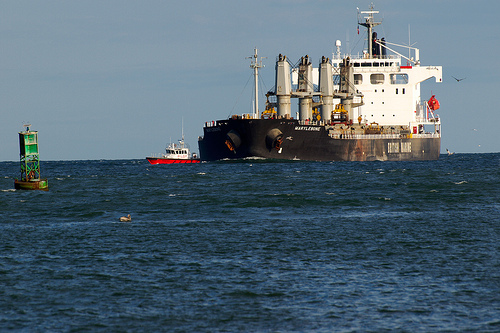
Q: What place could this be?
A: It is an ocean.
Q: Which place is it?
A: It is an ocean.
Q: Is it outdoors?
A: Yes, it is outdoors.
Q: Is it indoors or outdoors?
A: It is outdoors.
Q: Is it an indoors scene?
A: No, it is outdoors.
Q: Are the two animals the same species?
A: Yes, all the animals are birds.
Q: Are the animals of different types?
A: No, all the animals are birds.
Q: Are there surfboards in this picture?
A: No, there are no surfboards.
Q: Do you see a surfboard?
A: No, there are no surfboards.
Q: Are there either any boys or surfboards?
A: No, there are no surfboards or boys.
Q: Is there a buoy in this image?
A: Yes, there is a buoy.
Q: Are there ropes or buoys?
A: Yes, there is a buoy.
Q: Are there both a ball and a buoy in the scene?
A: No, there is a buoy but no balls.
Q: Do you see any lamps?
A: No, there are no lamps.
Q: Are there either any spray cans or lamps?
A: No, there are no lamps or spray cans.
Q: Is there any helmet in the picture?
A: No, there are no helmets.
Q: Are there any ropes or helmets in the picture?
A: No, there are no helmets or ropes.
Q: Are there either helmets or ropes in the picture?
A: No, there are no helmets or ropes.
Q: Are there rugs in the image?
A: No, there are no rugs.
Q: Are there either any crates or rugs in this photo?
A: No, there are no rugs or crates.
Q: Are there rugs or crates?
A: No, there are no rugs or crates.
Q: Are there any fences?
A: No, there are no fences.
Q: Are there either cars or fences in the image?
A: No, there are no fences or cars.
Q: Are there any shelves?
A: No, there are no shelves.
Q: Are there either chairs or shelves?
A: No, there are no shelves or chairs.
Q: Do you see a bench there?
A: No, there are no benches.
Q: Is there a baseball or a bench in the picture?
A: No, there are no benches or baseballs.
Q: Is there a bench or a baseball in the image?
A: No, there are no benches or baseballs.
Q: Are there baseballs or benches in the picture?
A: No, there are no benches or baseballs.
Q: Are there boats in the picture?
A: Yes, there is a boat.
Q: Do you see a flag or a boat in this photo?
A: Yes, there is a boat.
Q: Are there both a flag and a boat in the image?
A: No, there is a boat but no flags.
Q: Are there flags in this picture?
A: No, there are no flags.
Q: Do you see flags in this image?
A: No, there are no flags.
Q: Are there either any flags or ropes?
A: No, there are no flags or ropes.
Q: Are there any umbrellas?
A: No, there are no umbrellas.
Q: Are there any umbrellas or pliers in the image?
A: No, there are no umbrellas or pliers.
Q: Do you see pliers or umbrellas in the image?
A: No, there are no umbrellas or pliers.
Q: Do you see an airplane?
A: No, there are no airplanes.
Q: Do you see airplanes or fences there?
A: No, there are no airplanes or fences.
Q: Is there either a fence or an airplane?
A: No, there are no airplanes or fences.